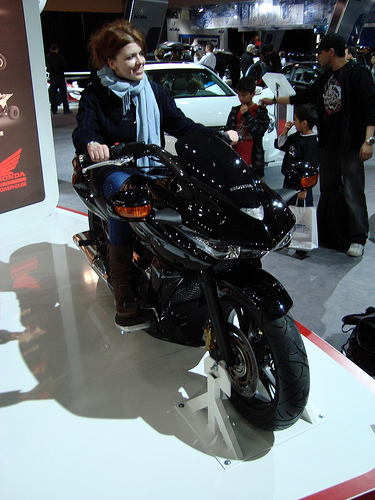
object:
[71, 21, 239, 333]
woman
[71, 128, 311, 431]
motorcycle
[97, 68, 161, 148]
blue scarf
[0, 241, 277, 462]
shadow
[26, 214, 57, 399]
ground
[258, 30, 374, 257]
man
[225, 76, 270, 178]
boy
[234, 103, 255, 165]
red shirt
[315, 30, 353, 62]
black cap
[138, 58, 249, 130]
white car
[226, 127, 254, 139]
bag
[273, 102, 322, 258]
boy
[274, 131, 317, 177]
black shirt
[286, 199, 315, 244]
bag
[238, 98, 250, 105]
chin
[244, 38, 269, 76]
guy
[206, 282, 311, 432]
front wheel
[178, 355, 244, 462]
display stand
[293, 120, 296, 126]
nose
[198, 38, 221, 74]
bloke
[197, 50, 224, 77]
white shirt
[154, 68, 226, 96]
windshield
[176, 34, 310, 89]
people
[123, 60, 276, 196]
car & bike show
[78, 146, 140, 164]
brake control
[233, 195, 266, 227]
light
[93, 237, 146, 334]
boots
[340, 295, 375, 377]
backpack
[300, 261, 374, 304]
floor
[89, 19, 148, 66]
red hair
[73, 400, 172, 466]
platform